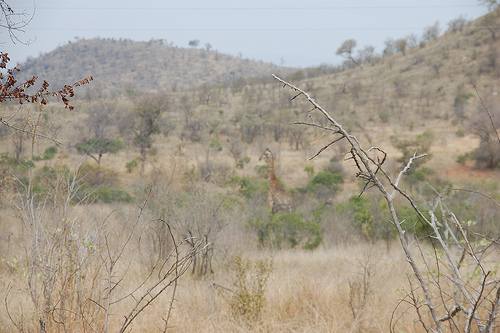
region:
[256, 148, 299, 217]
giraffe in a field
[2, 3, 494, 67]
blue sky above the hills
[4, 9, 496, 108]
hills in the background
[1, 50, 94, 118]
dried leaves on a tree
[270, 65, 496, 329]
dead branches from a tree or bush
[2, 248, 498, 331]
dried grass in the field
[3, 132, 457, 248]
some green foliage in the field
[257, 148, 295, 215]
giraffe is far away and blurry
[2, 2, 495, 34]
wires running through the area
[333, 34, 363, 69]
scraggly tree leaning over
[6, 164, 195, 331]
a leafless bush on the left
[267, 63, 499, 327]
a leafless bush on the right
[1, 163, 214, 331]
a dead plant on the left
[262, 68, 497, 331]
a dead plant on the right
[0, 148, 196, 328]
a dried out plant on the left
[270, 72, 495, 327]
a dried out plant on the right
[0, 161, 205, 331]
a dried out plant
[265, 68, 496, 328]
a dried out plant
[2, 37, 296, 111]
a hill in the distance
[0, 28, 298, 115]
a mountain in the distance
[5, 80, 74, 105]
A brownish dry twig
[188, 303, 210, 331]
Tuft of dry grass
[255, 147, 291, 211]
A giraffe standing upright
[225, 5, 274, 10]
An overhanging cable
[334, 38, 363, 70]
A leaning tree on a hill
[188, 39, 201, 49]
A tree atop a mound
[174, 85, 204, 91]
A valley between two hills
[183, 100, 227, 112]
Dry grass between shrubs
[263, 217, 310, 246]
Green shrubs sticking out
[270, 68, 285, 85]
The tip of a dry twig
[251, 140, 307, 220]
a lone giraffe in a field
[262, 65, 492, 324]
dry bush branches without leaves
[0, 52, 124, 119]
dead leaves on a tree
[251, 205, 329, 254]
a rare green bush in a field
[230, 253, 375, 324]
dried, brown grass in an open field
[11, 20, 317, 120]
a rolling hill in the background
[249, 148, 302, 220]
a giraffe standing in a field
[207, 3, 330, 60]
a clear blue sky on a sunny day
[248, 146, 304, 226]
a giraffe camouflaged by its surroundings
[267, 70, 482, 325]
a dead tree branch without leaves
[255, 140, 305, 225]
giraffe in the field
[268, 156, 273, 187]
neck of giraffe in photo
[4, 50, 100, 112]
branch with dead leaves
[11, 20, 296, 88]
hill in the distance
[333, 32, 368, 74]
tree on the hill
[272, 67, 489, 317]
empty branch on a tree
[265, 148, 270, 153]
giraffes ear on his head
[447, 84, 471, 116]
green leaves on a tree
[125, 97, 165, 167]
another tree in the distance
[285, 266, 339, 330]
dead grass in the field